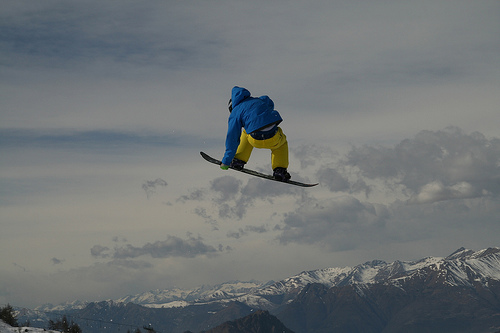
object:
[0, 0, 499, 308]
sky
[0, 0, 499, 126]
white clouds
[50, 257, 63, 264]
clouds